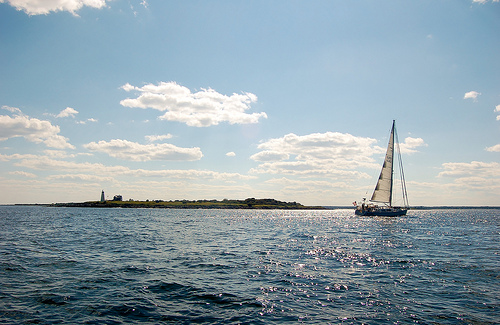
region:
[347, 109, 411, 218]
a blue and white boat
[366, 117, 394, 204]
a white sail on a boat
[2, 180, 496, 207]
a small island near the water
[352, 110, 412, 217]
a small boat near land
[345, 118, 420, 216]
a small blue boat near land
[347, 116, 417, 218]
a small white boat near an island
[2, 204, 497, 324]
a large body of water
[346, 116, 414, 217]
a boat on the water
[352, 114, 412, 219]
a boat on the calm water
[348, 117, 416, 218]
a blue boat on the calm water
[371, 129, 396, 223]
There is a sailboat visible here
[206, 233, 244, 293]
There is some blue water here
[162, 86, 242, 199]
There are some white, puffy clouds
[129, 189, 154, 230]
There is a patch of green land here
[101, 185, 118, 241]
There is a lighthouse visible here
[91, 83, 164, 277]
Jackson Mingus took this photo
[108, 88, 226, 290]
Zander Zeke owns this photo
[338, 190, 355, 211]
There is an American flag here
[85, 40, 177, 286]
This photo was taken in Boston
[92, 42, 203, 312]
This photo was taken on the East Coast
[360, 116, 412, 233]
sailboat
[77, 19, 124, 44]
white clouds in blue sky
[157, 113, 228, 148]
white clouds in blue sky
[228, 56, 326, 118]
white clouds in blue sky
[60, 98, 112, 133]
white clouds in blue sky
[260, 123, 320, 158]
white clouds in blue sky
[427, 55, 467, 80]
white clouds in blue sky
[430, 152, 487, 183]
white clouds in blue sky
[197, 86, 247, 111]
white clouds in blue sky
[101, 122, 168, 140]
white clouds in blue sky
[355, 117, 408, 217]
A boat on the water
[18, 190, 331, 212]
Land in the distance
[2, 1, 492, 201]
Clouds in the blue sky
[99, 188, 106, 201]
Lighthouse in the distance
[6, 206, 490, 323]
Deep blue water reflecting sunlight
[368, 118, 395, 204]
Sail on top of a boat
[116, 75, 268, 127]
Fluffy cloud in the sky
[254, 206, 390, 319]
Reflection of sunlight in the water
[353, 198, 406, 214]
A blue sail boat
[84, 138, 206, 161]
Fluffy white cloud in the sky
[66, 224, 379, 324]
The water is calm and blue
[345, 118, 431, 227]
A sailboat on the water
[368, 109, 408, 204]
The sail to the sailboat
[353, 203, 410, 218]
The boat is the color blue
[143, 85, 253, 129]
The clouds are white and fluffy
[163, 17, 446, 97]
The sky is clear and blue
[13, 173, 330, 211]
An island in the distance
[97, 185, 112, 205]
The light house on the land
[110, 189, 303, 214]
The grass on the island is green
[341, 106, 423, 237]
The boat is sailing in the ocean